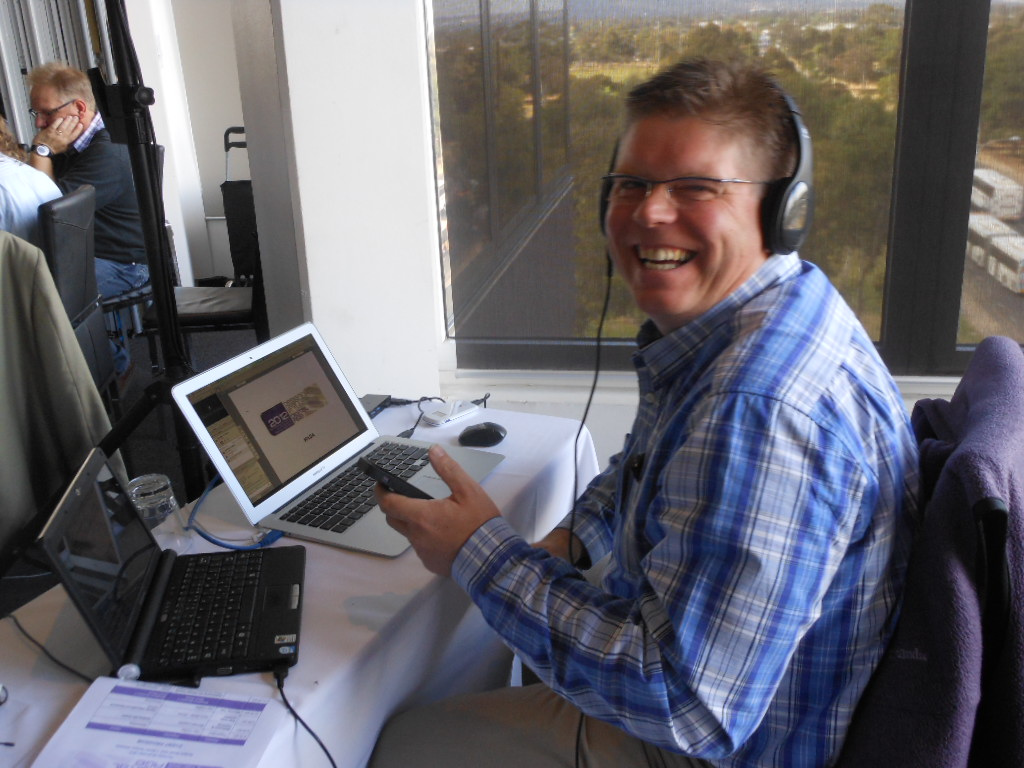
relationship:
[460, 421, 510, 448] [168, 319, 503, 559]
mouse for laptop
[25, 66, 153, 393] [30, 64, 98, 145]
man has head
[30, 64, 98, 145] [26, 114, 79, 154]
head in hand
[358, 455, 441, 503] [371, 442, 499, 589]
device on man's hand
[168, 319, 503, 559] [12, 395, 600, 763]
laptop on table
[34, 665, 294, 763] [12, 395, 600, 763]
booklet on table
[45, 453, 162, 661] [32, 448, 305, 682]
screen on laptop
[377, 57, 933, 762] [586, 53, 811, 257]
man with headset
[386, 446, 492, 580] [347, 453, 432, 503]
hand holding phone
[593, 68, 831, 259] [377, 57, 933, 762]
headphones on man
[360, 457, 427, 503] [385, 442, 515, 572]
phone in hand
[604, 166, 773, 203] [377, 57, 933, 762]
glasses on man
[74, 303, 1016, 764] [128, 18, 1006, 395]
furniture inside of building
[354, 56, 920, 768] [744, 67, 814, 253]
man wearing headset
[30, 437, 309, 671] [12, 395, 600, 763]
laptop on table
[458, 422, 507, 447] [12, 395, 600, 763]
mouse on table